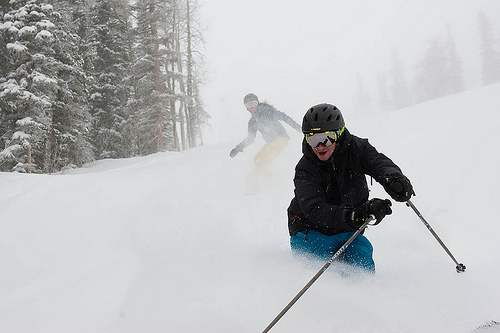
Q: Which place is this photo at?
A: It is at the field.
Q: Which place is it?
A: It is a field.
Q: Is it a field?
A: Yes, it is a field.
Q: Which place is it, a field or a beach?
A: It is a field.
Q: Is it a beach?
A: No, it is a field.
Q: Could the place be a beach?
A: No, it is a field.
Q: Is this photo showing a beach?
A: No, the picture is showing a field.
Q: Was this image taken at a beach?
A: No, the picture was taken in a field.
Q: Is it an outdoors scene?
A: Yes, it is outdoors.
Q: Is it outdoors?
A: Yes, it is outdoors.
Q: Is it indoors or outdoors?
A: It is outdoors.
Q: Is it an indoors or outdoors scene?
A: It is outdoors.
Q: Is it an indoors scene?
A: No, it is outdoors.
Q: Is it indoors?
A: No, it is outdoors.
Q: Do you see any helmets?
A: Yes, there is a helmet.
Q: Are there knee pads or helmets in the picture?
A: Yes, there is a helmet.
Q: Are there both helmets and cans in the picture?
A: No, there is a helmet but no cans.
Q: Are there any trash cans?
A: No, there are no trash cans.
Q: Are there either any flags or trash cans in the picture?
A: No, there are no trash cans or flags.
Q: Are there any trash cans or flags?
A: No, there are no trash cans or flags.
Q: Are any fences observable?
A: No, there are no fences.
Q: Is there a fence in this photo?
A: No, there are no fences.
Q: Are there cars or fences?
A: No, there are no fences or cars.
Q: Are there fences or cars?
A: No, there are no fences or cars.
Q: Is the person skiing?
A: Yes, the person is skiing.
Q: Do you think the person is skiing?
A: Yes, the person is skiing.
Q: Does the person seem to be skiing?
A: Yes, the person is skiing.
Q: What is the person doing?
A: The person is skiing.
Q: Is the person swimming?
A: No, the person is skiing.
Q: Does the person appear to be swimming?
A: No, the person is skiing.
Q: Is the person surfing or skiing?
A: The person is skiing.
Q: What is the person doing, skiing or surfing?
A: The person is skiing.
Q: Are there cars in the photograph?
A: No, there are no cars.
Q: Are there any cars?
A: No, there are no cars.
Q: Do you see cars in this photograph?
A: No, there are no cars.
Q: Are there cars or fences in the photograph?
A: No, there are no cars or fences.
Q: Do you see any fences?
A: No, there are no fences.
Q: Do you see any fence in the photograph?
A: No, there are no fences.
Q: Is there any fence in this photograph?
A: No, there are no fences.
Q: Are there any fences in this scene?
A: No, there are no fences.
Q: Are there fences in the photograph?
A: No, there are no fences.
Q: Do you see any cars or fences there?
A: No, there are no fences or cars.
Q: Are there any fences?
A: No, there are no fences.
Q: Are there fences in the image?
A: No, there are no fences.